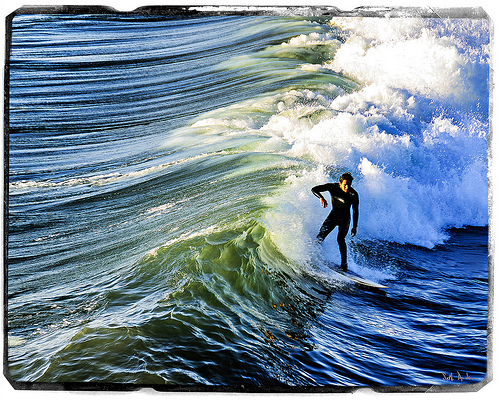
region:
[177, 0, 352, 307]
green in ocean waves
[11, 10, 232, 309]
streaks in the ocean waves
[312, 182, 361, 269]
a black wetsuit on a man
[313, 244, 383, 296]
a white surfboard under a man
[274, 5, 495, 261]
white rushing wave water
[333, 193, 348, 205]
a logo on the front of the wetsuit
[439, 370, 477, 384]
image credit in the corner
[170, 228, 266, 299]
a green wavy section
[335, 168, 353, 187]
dark brown hair on the man's head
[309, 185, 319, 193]
a bent right elbow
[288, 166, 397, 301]
person standing on a surfboard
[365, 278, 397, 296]
pointy tip of the board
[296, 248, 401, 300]
board sticking out of the water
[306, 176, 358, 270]
person wearing a black wetsuit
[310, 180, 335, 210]
arm bent at the elbow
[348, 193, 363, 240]
arm hanging down by the sid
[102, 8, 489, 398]
man surfing a wave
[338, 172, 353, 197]
head is turned to the side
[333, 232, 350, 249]
knee is slightly bent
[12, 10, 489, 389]
blue body of water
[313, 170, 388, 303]
a surfer riding the ocean waves.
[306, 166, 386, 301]
a surfer riding the ocean waves.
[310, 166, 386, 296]
a surfer riding the ocean waves.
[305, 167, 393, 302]
a surfer riding the ocean waves.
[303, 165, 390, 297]
a surfer riding the ocean waves.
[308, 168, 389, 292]
a surfer riding the ocean waves.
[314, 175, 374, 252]
his wetsuit is black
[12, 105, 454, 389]
the ocean changes colors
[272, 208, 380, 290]
surfing on a wave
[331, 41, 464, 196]
wave produces white foam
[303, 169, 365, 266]
he is wearing a wetsuit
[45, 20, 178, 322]
the ocean produces many lines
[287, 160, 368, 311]
he is surfing on a wave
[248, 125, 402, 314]
surfing in the ocean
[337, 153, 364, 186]
his hair is brown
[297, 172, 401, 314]
person standing on a surfboard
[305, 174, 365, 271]
man wearing a wetsuit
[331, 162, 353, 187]
man has brown hair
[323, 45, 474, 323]
the wave is white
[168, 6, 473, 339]
the water is wavy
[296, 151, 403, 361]
the man is surfing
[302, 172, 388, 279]
the wet suit is black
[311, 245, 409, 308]
the surfboard is white